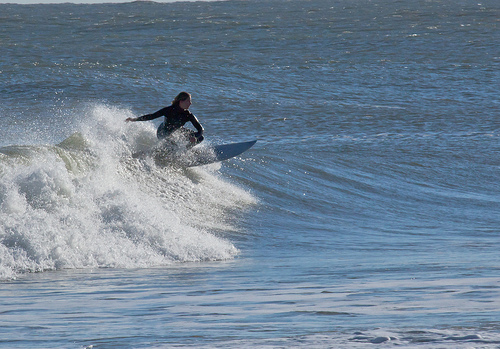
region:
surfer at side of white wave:
[3, 86, 256, 273]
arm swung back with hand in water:
[112, 87, 177, 142]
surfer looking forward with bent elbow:
[175, 86, 210, 136]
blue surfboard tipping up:
[162, 131, 259, 170]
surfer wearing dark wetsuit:
[125, 105, 205, 145]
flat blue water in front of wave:
[0, 252, 486, 337]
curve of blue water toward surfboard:
[230, 136, 492, 251]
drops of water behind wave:
[6, 76, 93, 156]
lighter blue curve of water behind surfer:
[5, 51, 285, 107]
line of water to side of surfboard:
[225, 126, 490, 156]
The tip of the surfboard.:
[227, 136, 261, 149]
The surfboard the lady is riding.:
[135, 139, 264, 164]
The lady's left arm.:
[121, 108, 166, 123]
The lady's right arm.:
[186, 114, 207, 134]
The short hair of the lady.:
[175, 90, 187, 105]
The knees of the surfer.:
[175, 129, 202, 151]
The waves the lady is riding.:
[9, 112, 242, 266]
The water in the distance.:
[11, 0, 498, 143]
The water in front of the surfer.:
[2, 227, 492, 347]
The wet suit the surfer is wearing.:
[137, 103, 208, 158]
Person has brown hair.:
[170, 83, 195, 106]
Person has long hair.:
[161, 85, 207, 112]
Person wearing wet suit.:
[127, 102, 240, 177]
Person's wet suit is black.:
[150, 89, 221, 159]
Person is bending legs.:
[142, 109, 251, 219]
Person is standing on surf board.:
[140, 125, 232, 173]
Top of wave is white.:
[27, 142, 155, 225]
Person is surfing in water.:
[111, 55, 258, 215]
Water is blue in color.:
[328, 205, 405, 327]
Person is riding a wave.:
[99, 75, 256, 201]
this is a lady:
[155, 80, 214, 152]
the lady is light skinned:
[176, 101, 193, 110]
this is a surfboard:
[213, 135, 261, 159]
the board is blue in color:
[219, 140, 251, 156]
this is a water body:
[320, 127, 467, 293]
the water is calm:
[341, 146, 412, 240]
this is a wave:
[43, 120, 111, 228]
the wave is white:
[76, 139, 132, 211]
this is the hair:
[169, 85, 184, 103]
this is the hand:
[122, 103, 157, 128]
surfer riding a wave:
[125, 88, 256, 166]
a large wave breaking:
[0, 111, 254, 261]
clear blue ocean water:
[1, 4, 498, 339]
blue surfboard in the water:
[117, 140, 257, 167]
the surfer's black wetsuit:
[135, 105, 202, 147]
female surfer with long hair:
[120, 88, 202, 153]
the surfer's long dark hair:
[172, 91, 187, 105]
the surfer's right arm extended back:
[125, 106, 165, 121]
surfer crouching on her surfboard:
[126, 90, 258, 167]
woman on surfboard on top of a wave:
[118, 90, 258, 170]